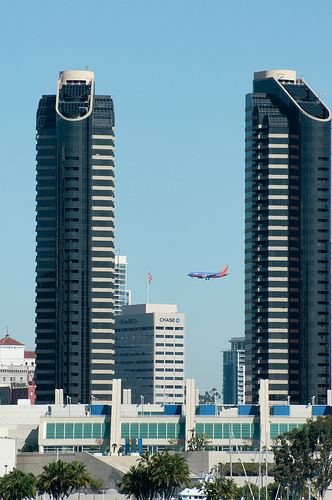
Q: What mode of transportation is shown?
A: Plane.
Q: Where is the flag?
A: Building roof.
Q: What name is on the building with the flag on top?
A: CHASE.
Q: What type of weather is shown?
A: Clear.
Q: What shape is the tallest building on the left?
A: Rectangle.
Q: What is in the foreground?
A: Trees.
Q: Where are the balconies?
A: On the two tallest buildings.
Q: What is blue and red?
A: The plane.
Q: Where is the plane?
A: In the sky.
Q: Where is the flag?
A: On the building.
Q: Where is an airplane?
A: Flying between two buildings.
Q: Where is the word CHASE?
A: On short white building.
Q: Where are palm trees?
A: Palm trees are in the foreground.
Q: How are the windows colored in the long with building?
A: Windows are green.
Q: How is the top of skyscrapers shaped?
A: Like a u.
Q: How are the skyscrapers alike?
A: They are identical.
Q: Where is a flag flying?
A: Top of CHASE building.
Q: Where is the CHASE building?
A: Between two skyscrapers.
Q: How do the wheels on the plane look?
A: Wheels are down.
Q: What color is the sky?
A: Blue.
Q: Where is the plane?
A: Between the buildings.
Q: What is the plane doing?
A: Flying.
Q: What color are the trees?
A: Green.